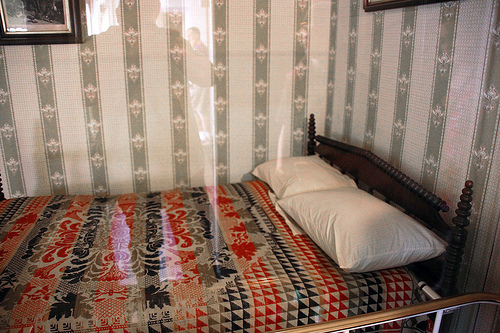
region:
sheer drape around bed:
[81, 47, 256, 135]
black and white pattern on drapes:
[107, 25, 172, 115]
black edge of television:
[48, 12, 98, 47]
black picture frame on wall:
[349, 2, 410, 18]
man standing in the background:
[171, 15, 235, 133]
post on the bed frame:
[296, 105, 320, 142]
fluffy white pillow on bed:
[272, 191, 442, 267]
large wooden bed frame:
[310, 128, 455, 208]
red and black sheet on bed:
[101, 226, 279, 270]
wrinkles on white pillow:
[291, 200, 349, 240]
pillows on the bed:
[256, 150, 407, 285]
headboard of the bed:
[339, 133, 439, 218]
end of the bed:
[453, 168, 490, 257]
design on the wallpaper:
[123, 68, 147, 84]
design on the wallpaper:
[124, 102, 139, 123]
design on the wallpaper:
[168, 148, 191, 165]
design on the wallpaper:
[166, 115, 198, 132]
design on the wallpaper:
[206, 132, 228, 157]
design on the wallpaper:
[203, 95, 230, 116]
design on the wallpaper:
[249, 80, 269, 104]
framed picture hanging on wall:
[0, 2, 85, 47]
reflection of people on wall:
[71, 6, 212, 193]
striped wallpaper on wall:
[1, 6, 323, 193]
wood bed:
[0, 115, 475, 331]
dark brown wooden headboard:
[305, 114, 475, 299]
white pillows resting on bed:
[251, 155, 447, 272]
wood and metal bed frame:
[278, 293, 487, 332]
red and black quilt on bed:
[1, 180, 428, 332]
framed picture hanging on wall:
[358, 0, 448, 12]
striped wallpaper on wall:
[328, 4, 498, 327]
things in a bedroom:
[0, 0, 495, 330]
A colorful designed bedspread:
[6, 177, 258, 331]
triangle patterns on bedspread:
[253, 275, 310, 326]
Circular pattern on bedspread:
[6, 190, 266, 315]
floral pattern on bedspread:
[120, 246, 166, 277]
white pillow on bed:
[282, 187, 440, 268]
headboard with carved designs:
[303, 111, 385, 155]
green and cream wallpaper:
[0, 1, 499, 146]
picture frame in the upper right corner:
[0, 0, 87, 44]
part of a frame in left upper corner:
[351, 0, 463, 11]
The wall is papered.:
[1, 2, 499, 332]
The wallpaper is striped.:
[1, 2, 498, 326]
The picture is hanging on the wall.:
[1, 0, 173, 140]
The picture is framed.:
[0, 0, 145, 112]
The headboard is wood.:
[296, 110, 483, 305]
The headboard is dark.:
[297, 103, 484, 307]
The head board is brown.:
[291, 103, 484, 300]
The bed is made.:
[1, 105, 496, 330]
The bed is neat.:
[1, 98, 487, 330]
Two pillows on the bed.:
[114, 100, 498, 331]